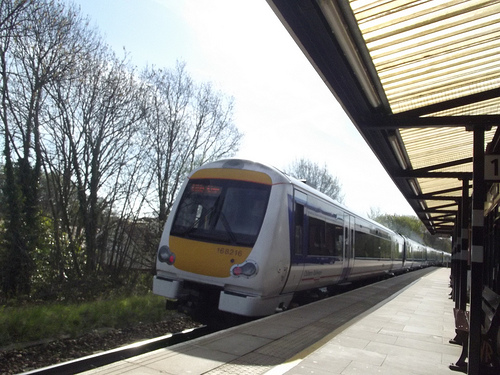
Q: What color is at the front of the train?
A: White and yellow.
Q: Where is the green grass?
A: Next to the train.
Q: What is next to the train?
A: The train platform.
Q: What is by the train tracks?
A: Gravel.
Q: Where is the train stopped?
A: At the train station.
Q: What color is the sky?
A: Blue.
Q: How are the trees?
A: Barren.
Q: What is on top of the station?
A: A roof.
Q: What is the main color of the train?
A: White.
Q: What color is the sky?
A: Blue.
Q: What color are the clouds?
A: White.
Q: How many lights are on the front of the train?
A: 4.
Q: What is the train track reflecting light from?
A: Sun.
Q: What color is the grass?
A: Green.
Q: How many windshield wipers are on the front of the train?
A: 2.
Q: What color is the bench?
A: Brown.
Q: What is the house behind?
A: Trees.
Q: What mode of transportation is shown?
A: Train.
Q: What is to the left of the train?
A: Trees.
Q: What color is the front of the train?
A: Yellow and white.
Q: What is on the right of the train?
A: Walkway.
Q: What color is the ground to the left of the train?
A: Green.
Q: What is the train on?
A: Track.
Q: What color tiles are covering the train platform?
A: Gray.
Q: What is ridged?
A: Roof.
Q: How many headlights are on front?
A: Two.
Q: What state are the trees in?
A: Bare.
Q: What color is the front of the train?
A: Yellow.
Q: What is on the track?
A: A train.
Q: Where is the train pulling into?
A: A station.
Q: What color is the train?
A: Yellow & white.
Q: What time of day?
A: Morning or afternoon.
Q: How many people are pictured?
A: None.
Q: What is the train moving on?
A: A rail.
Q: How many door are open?
A: None.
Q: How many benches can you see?
A: One.